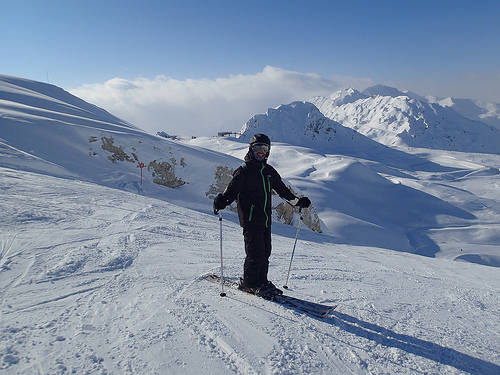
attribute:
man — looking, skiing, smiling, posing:
[214, 128, 311, 295]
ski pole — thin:
[283, 208, 302, 291]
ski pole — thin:
[215, 212, 227, 303]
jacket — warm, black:
[219, 159, 300, 232]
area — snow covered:
[1, 69, 499, 374]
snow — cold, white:
[3, 169, 498, 375]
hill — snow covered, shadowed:
[234, 98, 378, 155]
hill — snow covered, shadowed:
[332, 85, 493, 148]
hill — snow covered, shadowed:
[1, 70, 218, 192]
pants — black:
[239, 222, 274, 282]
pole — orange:
[136, 162, 145, 190]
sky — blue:
[1, 1, 499, 116]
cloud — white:
[78, 64, 499, 150]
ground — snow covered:
[1, 199, 498, 373]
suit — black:
[221, 162, 298, 283]